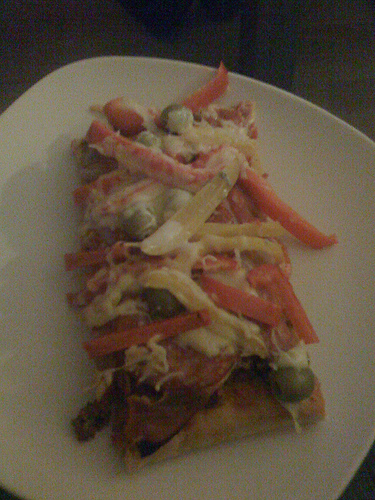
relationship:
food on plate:
[76, 70, 338, 461] [4, 60, 373, 499]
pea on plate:
[274, 367, 314, 399] [4, 60, 373, 499]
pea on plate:
[143, 279, 182, 318] [4, 60, 373, 499]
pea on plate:
[124, 209, 157, 243] [4, 60, 373, 499]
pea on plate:
[163, 105, 193, 133] [4, 60, 373, 499]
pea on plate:
[131, 127, 157, 152] [4, 60, 373, 499]